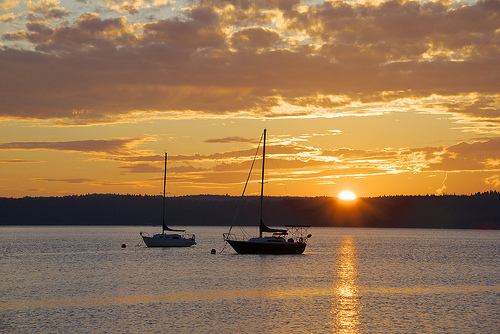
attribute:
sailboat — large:
[224, 127, 311, 253]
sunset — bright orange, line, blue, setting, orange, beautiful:
[1, 1, 499, 198]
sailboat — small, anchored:
[139, 152, 197, 248]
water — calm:
[1, 255, 500, 332]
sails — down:
[260, 222, 290, 235]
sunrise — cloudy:
[0, 2, 499, 331]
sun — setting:
[338, 187, 358, 204]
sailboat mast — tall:
[256, 128, 269, 240]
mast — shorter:
[161, 152, 171, 234]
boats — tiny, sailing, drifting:
[139, 128, 313, 255]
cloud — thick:
[1, 45, 500, 125]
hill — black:
[369, 192, 479, 216]